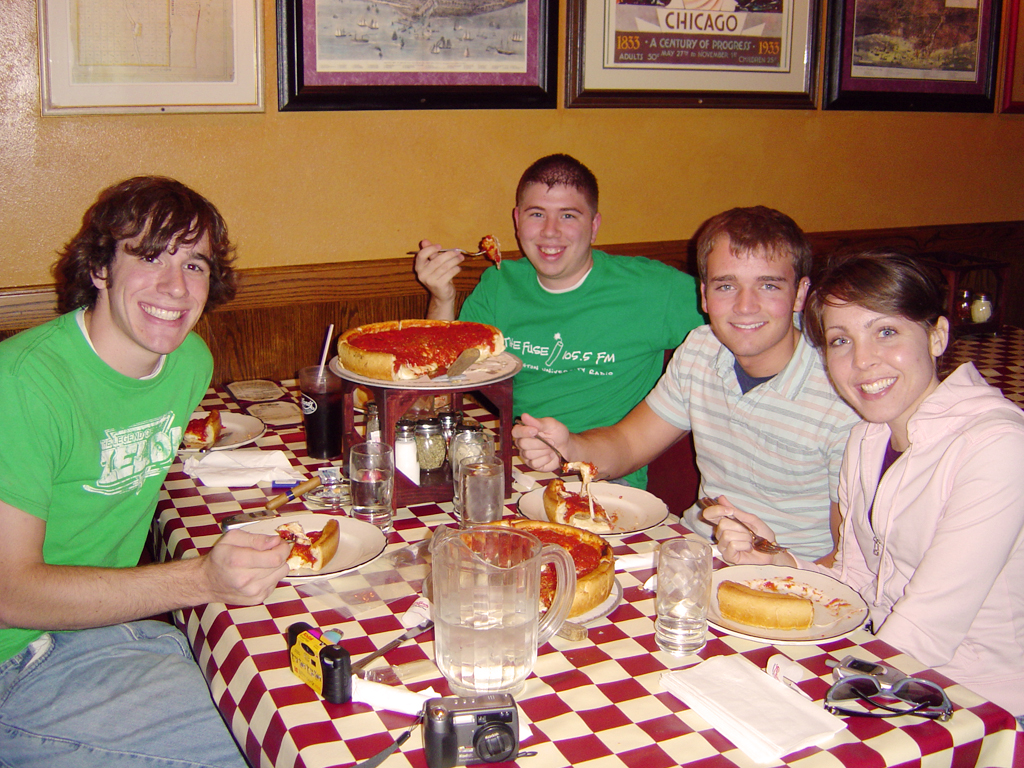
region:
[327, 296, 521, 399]
Deep-dish pizza on the plate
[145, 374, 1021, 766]
Red and white checkered tablecloth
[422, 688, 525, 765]
Camera on the table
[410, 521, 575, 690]
Pitcher of water on the table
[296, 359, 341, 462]
Glass of cola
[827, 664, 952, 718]
Sunglasses on the table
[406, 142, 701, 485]
Boy holding a fork with a piece of pizza on it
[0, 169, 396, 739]
Man in a green shirt eating pizza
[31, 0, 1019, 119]
Photos on the wall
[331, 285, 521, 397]
a pizza above the shakers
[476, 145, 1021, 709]
three people sitting on one side of the table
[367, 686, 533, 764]
a silver camera on the table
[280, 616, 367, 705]
a disposable camera on the table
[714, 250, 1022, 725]
one person is a woman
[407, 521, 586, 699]
a pitcher of water on the table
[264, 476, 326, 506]
a cigar on the table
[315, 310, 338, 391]
a straw in the glass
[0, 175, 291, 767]
man with curly brown hair sitting in a chair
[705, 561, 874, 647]
pizza crust on a white plate with red border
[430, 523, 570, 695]
a pitcher of cold ice water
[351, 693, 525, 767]
a silver camera with a black zoom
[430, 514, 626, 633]
a small pizza on a white plate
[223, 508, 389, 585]
a pizza slice on a white plate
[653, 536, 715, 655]
a glass filled with ice water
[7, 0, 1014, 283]
framed pictures on a yellow wall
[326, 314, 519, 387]
a pizza with tomato sauce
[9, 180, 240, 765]
a person is sitting down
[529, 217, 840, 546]
a person is sitting down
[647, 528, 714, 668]
a vessel made for drinking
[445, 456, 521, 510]
a vessel made for drinking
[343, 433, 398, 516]
a vessel made for drinking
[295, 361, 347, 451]
a vessel made for drinking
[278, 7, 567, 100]
a picture in a frame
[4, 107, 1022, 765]
four people sitting at table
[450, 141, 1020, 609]
Three people sitting at table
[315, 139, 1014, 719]
three people eating pizza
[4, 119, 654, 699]
two young men eating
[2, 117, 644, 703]
two young men eating pizza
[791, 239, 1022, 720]
red head sitting at table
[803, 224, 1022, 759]
red haired girl at table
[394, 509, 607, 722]
pitcher of water sitting on table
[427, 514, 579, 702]
pitcher of water sitting on checkered table cloth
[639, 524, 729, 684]
glass of water sitting on table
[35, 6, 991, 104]
pictures on the wall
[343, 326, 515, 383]
a pizza on the table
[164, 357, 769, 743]
a red and white table cloth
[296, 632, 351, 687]
a yellow camera on the table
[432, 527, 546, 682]
a pitcher of water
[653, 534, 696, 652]
a glass on the table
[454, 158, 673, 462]
a man in a green shirt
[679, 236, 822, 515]
a man in a striped shirt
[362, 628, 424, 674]
a knife on the table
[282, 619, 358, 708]
yellow and black disposable camera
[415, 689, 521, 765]
silver digital camera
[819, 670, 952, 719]
blue folded sunglasses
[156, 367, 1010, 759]
red and white checkered tablecloth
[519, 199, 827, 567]
young man in striped shirt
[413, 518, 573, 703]
plastic pitcher of water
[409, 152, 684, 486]
man holding fork up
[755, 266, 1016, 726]
A person is sitting down